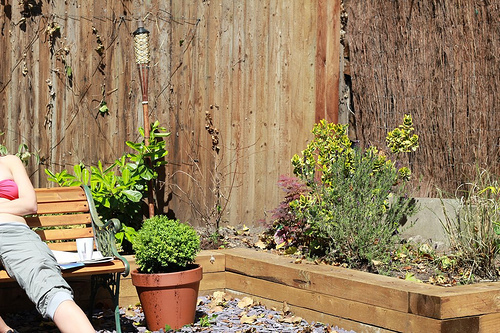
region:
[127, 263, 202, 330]
Terracotta colored flower pot with plant in it.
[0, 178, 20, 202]
Pink tube top on a woman.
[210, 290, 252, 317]
Tan leaves in the gravel near a pot.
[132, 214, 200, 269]
Green plant in a terracotta pot.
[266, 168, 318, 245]
Part of a purple bush.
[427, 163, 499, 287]
Decorative green and brown grass on the far right.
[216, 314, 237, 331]
Pieces of gravel near a terracotta pot.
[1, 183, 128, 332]
A wood and metal bench.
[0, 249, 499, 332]
Wooden flower bed with plants and flowers inside.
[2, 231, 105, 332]
Left leg of a sitting woman.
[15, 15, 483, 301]
Picture taken during the day.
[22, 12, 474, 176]
Picture is taken outside.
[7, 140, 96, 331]
A woman sits on a bench.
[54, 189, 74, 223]
The bench is made of wood.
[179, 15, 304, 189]
The fence is made of wood.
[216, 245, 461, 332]
The planters are made of wood.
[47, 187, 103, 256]
The bench is made of wood and metal.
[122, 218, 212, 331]
A plant is in a stand-alone planter.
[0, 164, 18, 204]
The woman's bikini top is pink.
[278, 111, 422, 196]
The plant has yellow flowers.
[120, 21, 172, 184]
tiki torch by wood fence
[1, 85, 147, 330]
woman on a bench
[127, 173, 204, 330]
green shrubbery in a pot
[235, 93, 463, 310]
flowers behind wooden flower box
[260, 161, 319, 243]
small purple bush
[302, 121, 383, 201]
yellow flowers on bush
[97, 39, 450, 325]
yard with flowers and plants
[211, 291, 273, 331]
leaves on the ground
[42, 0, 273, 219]
wooden privacy fence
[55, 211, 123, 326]
drink sitting on bench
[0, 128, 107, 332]
Half of a person is in the image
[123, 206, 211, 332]
A plant is in a orange pot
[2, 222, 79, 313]
Person is wearing gray pants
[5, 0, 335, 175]
A wooden fence is in the background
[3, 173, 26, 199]
Person is wearing a pink top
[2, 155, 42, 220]
Person's arm is on their stomach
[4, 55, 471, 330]
Photo was taken in the daytime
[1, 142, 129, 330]
Person is sitting on a bench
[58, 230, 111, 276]
A white cup is on the bench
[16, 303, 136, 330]
Bench is casting a shadow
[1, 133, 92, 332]
lady sitting on bench wearing hot pink tube top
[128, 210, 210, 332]
light green plant in terracotta pot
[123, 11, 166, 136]
tiki torch in front of wooden fence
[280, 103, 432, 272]
pale yellow and green flowers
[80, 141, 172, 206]
light and dark green plant in front of wooden fence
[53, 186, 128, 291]
edge of wooden and metal bench with coffee cup perched on it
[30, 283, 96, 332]
calf of a Caucasian woman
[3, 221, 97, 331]
outstretched leg of woman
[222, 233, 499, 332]
long wooden planter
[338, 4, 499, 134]
section of wide tree trunk